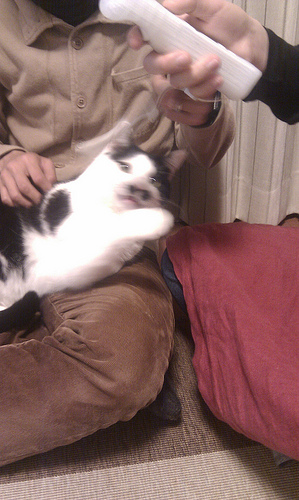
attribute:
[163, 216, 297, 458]
shirt — Red 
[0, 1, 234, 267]
shirt — Brown, buttoned